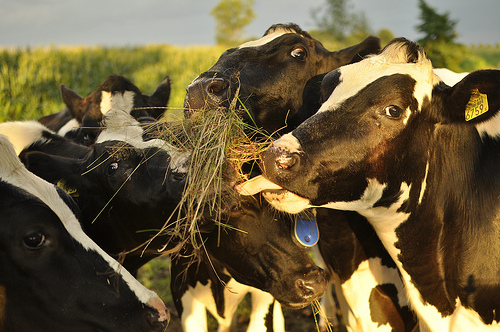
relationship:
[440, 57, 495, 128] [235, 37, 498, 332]
tag on cow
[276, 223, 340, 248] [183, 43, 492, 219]
blue tag on cow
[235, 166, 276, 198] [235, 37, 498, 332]
tongue on cow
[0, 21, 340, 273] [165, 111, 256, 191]
cows eating hay patch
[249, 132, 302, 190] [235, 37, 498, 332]
nose of cow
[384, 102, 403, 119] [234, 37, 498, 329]
eye of cow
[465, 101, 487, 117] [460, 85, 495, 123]
number on tag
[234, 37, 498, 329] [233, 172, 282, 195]
cow sticking out tongue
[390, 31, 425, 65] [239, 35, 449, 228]
hair of head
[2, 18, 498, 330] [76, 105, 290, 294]
cows eating straw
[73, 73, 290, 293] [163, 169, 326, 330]
hay for cow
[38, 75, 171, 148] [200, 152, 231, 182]
cows behind straw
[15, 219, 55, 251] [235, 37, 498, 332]
eye on cow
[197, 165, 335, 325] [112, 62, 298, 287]
cow under straw pile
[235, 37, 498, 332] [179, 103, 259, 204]
cow eating straw